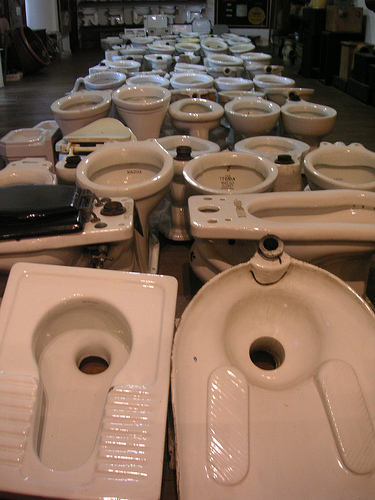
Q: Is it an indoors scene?
A: Yes, it is indoors.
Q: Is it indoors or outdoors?
A: It is indoors.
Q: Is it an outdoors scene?
A: No, it is indoors.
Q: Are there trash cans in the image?
A: No, there are no trash cans.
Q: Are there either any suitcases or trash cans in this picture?
A: No, there are no trash cans or suitcases.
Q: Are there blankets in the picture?
A: No, there are no blankets.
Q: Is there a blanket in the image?
A: No, there are no blankets.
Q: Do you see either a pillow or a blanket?
A: No, there are no blankets or pillows.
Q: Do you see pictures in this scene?
A: No, there are no pictures.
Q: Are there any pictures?
A: No, there are no pictures.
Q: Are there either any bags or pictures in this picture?
A: No, there are no pictures or bags.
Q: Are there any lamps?
A: No, there are no lamps.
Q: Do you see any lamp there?
A: No, there are no lamps.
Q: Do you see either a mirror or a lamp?
A: No, there are no lamps or mirrors.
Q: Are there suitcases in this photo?
A: No, there are no suitcases.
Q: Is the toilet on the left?
A: Yes, the toilet is on the left of the image.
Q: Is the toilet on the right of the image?
A: No, the toilet is on the left of the image.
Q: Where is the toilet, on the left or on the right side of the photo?
A: The toilet is on the left of the image.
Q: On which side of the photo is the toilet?
A: The toilet is on the left of the image.